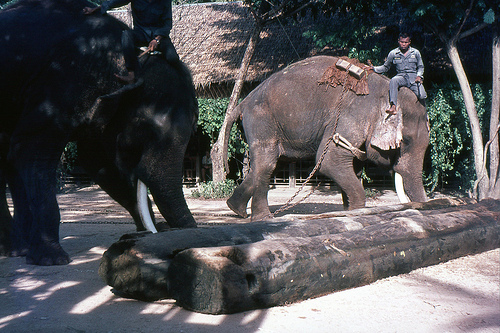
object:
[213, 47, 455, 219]
elephant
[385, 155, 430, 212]
tusk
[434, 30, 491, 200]
tree trunk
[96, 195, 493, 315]
log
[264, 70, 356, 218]
chain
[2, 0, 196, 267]
elephant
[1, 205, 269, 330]
shadow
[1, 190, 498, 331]
ground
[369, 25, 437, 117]
man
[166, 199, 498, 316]
tree log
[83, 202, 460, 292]
poles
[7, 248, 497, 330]
dirt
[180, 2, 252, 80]
straw hut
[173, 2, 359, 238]
background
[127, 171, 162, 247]
elephant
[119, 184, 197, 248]
tusk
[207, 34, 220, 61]
straw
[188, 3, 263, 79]
roof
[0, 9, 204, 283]
chain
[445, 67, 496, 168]
tree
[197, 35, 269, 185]
tree trunk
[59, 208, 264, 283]
shade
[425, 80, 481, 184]
bush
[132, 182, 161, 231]
task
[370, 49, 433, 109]
clothing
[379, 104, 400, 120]
shoes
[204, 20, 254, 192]
tree